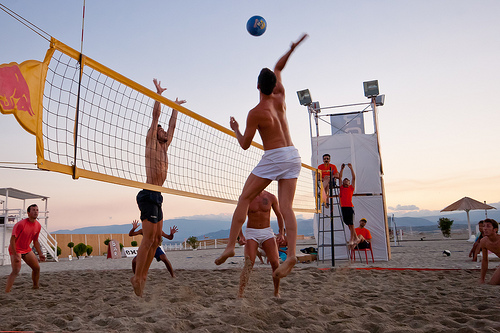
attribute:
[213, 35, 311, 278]
man — playing volleyball, a hunk, jumping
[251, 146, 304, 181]
shorts — wrinkled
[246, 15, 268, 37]
ball — being hit, in air, blue, yellow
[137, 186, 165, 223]
shorts — black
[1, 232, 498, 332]
sand — brown, footprinted, textured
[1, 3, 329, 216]
net — large, yellow, volleyball net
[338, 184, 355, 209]
shirt — orange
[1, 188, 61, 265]
life guard stand — white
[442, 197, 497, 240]
umbrella — brown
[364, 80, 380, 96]
flood light — large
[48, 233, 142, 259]
barrier — long, large, in distance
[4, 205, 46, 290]
man — playing volleyball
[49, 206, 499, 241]
mountain range — in distance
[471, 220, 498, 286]
man — crouching, kneeling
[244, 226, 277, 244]
shorts — white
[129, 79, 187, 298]
man — jumping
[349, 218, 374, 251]
man — sitting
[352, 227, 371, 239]
shirt — red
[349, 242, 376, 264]
chair — red